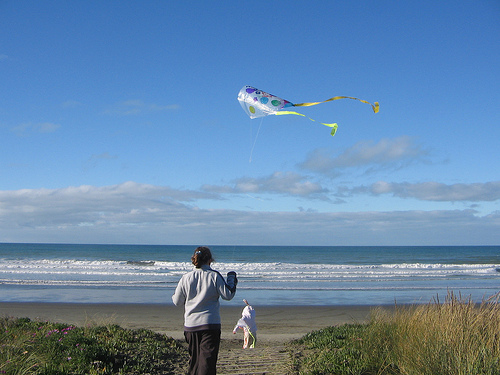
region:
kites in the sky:
[218, 77, 395, 150]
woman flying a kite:
[165, 238, 242, 365]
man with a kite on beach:
[228, 295, 263, 355]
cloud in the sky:
[383, 177, 488, 208]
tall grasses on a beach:
[380, 298, 493, 371]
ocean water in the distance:
[234, 242, 498, 301]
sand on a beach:
[271, 306, 331, 337]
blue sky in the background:
[32, 79, 147, 161]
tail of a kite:
[322, 82, 390, 117]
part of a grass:
[478, 305, 484, 309]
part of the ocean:
[298, 258, 332, 343]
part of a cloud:
[344, 215, 347, 232]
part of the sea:
[350, 270, 356, 286]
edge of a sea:
[304, 308, 308, 323]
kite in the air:
[234, 78, 385, 134]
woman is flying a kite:
[163, 248, 237, 372]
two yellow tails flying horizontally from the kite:
[275, 97, 382, 131]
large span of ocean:
[1, 241, 493, 300]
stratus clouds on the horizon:
[9, 143, 498, 237]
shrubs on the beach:
[5, 312, 183, 374]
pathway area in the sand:
[186, 332, 291, 373]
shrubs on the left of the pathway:
[284, 298, 499, 370]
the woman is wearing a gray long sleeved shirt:
[167, 263, 238, 330]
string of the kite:
[215, 108, 261, 282]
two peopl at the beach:
[176, 216, 274, 374]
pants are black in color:
[144, 291, 220, 367]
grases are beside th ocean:
[316, 298, 463, 374]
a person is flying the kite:
[233, 299, 271, 361]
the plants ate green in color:
[86, 303, 153, 373]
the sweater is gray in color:
[166, 276, 233, 328]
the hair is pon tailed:
[167, 229, 232, 276]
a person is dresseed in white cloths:
[239, 302, 275, 374]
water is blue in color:
[296, 247, 326, 267]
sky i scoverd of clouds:
[234, 189, 285, 226]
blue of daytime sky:
[0, 2, 499, 242]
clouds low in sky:
[0, 133, 496, 243]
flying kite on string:
[233, 85, 380, 270]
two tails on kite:
[285, 93, 382, 134]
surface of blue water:
[0, 245, 497, 262]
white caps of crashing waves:
[1, 260, 498, 290]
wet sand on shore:
[1, 291, 495, 326]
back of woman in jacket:
[172, 247, 237, 372]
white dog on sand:
[231, 300, 258, 350]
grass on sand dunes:
[5, 322, 493, 372]